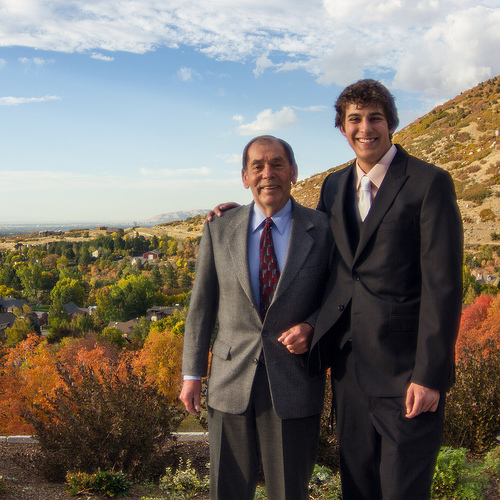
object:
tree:
[455, 289, 499, 369]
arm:
[410, 172, 465, 384]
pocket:
[209, 335, 233, 363]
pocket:
[379, 312, 421, 349]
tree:
[86, 286, 129, 327]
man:
[306, 77, 466, 498]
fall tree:
[467, 292, 500, 365]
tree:
[452, 131, 470, 146]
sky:
[0, 0, 500, 229]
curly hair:
[333, 75, 402, 140]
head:
[333, 73, 401, 162]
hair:
[334, 77, 399, 143]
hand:
[206, 202, 242, 222]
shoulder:
[201, 202, 248, 236]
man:
[178, 133, 332, 498]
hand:
[275, 320, 313, 356]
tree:
[26, 357, 189, 493]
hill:
[0, 434, 500, 499]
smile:
[350, 132, 381, 147]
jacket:
[180, 196, 333, 417]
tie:
[257, 217, 281, 319]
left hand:
[402, 380, 440, 423]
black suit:
[308, 143, 465, 400]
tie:
[355, 171, 372, 223]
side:
[398, 257, 423, 380]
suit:
[309, 142, 466, 498]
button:
[333, 301, 345, 315]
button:
[349, 269, 365, 283]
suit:
[181, 196, 335, 500]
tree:
[443, 337, 500, 454]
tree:
[0, 331, 74, 435]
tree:
[132, 322, 182, 401]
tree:
[75, 340, 116, 384]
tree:
[50, 333, 118, 416]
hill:
[148, 74, 500, 283]